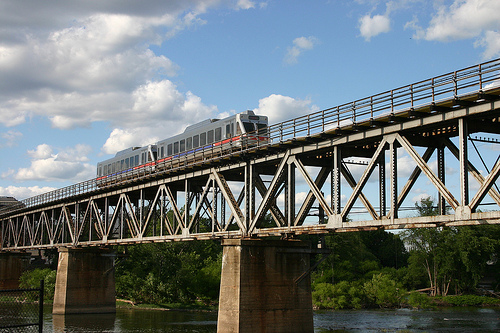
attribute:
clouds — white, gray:
[1, 0, 206, 188]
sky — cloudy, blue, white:
[8, 12, 482, 146]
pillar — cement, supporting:
[215, 236, 318, 328]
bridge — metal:
[5, 67, 489, 240]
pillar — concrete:
[52, 248, 120, 308]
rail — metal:
[116, 60, 499, 155]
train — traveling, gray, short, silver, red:
[91, 107, 274, 194]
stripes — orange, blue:
[100, 139, 253, 183]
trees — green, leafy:
[117, 245, 214, 301]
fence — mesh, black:
[0, 276, 46, 331]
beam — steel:
[304, 123, 490, 228]